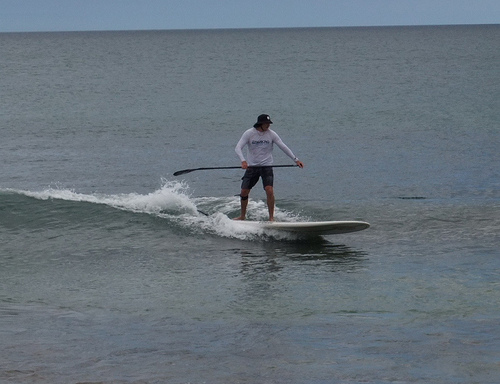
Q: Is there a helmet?
A: No, there are no helmets.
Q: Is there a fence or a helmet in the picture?
A: No, there are no helmets or fences.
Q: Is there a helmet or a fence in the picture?
A: No, there are no helmets or fences.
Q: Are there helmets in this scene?
A: No, there are no helmets.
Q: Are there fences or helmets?
A: No, there are no helmets or fences.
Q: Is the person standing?
A: Yes, the person is standing.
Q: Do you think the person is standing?
A: Yes, the person is standing.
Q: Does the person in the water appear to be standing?
A: Yes, the person is standing.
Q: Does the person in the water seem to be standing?
A: Yes, the person is standing.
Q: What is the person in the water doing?
A: The person is standing.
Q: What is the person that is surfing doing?
A: The person is standing.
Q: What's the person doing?
A: The person is standing.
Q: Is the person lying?
A: No, the person is standing.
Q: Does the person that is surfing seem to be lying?
A: No, the person is standing.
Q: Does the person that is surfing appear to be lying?
A: No, the person is standing.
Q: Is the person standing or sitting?
A: The person is standing.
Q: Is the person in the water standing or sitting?
A: The person is standing.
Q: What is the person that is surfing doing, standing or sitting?
A: The person is standing.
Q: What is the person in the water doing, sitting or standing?
A: The person is standing.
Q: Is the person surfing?
A: Yes, the person is surfing.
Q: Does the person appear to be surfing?
A: Yes, the person is surfing.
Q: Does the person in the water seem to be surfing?
A: Yes, the person is surfing.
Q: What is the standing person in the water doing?
A: The person is surfing.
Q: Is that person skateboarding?
A: No, the person is surfing.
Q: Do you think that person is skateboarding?
A: No, the person is surfing.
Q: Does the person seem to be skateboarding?
A: No, the person is surfing.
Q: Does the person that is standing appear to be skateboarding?
A: No, the person is surfing.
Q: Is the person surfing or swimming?
A: The person is surfing.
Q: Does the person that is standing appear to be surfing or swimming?
A: The person is surfing.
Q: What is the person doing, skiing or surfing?
A: The person is surfing.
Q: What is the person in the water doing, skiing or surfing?
A: The person is surfing.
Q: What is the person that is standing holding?
A: The person is holding the paddle.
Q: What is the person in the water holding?
A: The person is holding the paddle.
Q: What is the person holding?
A: The person is holding the paddle.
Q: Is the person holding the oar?
A: Yes, the person is holding the oar.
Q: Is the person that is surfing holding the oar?
A: Yes, the person is holding the oar.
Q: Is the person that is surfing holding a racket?
A: No, the person is holding the oar.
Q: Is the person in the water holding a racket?
A: No, the person is holding the oar.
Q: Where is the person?
A: The person is in the water.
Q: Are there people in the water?
A: Yes, there is a person in the water.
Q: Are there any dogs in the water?
A: No, there is a person in the water.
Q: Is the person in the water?
A: Yes, the person is in the water.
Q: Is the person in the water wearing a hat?
A: Yes, the person is wearing a hat.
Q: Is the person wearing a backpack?
A: No, the person is wearing a hat.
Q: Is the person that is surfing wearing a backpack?
A: No, the person is wearing a hat.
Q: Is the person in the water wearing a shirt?
A: Yes, the person is wearing a shirt.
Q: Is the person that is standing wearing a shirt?
A: Yes, the person is wearing a shirt.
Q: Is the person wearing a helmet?
A: No, the person is wearing a shirt.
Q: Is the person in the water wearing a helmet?
A: No, the person is wearing a shirt.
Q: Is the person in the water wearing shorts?
A: Yes, the person is wearing shorts.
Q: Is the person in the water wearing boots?
A: No, the person is wearing shorts.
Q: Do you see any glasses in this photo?
A: No, there are no glasses.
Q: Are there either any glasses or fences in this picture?
A: No, there are no glasses or fences.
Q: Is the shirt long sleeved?
A: Yes, the shirt is long sleeved.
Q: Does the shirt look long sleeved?
A: Yes, the shirt is long sleeved.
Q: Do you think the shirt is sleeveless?
A: No, the shirt is long sleeved.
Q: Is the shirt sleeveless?
A: No, the shirt is long sleeved.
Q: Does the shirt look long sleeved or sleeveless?
A: The shirt is long sleeved.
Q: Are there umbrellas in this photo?
A: No, there are no umbrellas.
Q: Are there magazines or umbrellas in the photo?
A: No, there are no umbrellas or magazines.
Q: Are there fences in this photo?
A: No, there are no fences.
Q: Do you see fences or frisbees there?
A: No, there are no fences or frisbees.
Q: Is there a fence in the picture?
A: No, there are no fences.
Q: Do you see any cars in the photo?
A: No, there are no cars.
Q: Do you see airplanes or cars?
A: No, there are no cars or airplanes.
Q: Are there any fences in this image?
A: No, there are no fences.